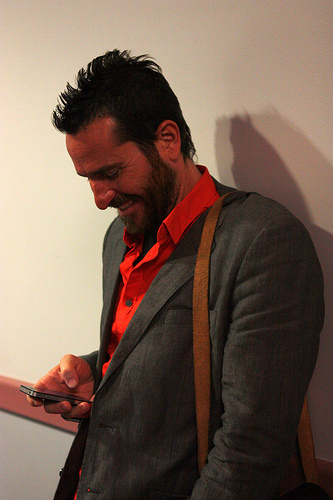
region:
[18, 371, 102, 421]
Small black mobile phone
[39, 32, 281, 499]
Man wearing a red shirt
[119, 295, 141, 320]
Small grey button on shirt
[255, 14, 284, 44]
PArt of white wall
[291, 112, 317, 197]
Part of white wall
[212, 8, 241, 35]
Part of white wall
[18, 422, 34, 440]
Part of white wall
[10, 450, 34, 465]
Part of white wall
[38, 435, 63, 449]
Part of white wall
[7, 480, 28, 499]
Part of white wall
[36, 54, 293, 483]
This is a man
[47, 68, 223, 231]
The man is smiling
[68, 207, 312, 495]
The man is wearing a blazer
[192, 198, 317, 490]
The man is holding a bag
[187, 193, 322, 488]
The bag has a brown strap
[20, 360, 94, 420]
The man is holding a cell phone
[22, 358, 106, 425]
The cell phone is in the man's right hand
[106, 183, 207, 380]
The man has a red shirt under his blazer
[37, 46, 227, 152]
The man's hair is styled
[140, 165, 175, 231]
The man has a beard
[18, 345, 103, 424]
hand holding electronic device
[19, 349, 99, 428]
cell phone in a hand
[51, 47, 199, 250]
dark haired man smiling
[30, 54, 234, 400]
person with a beard and mustache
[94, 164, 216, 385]
orange shirt with buttons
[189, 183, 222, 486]
long brown shouder strap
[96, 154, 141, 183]
eye with crow's feet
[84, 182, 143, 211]
mustache under a nose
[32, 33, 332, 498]
man leaning against a wall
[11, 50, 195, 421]
man looking at cell phone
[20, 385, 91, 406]
The Iphone in the mans hands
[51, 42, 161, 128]
The guys fauxhawk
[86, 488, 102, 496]
The button holes on the mans jacket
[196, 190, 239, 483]
The strap of the mans bag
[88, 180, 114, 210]
The mans nose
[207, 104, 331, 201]
The shadow of the man on the wall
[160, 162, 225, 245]
The collar of the mans shirt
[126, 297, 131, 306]
The buttons on the mans red shirt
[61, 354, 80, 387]
The mans bent thumb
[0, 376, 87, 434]
The pink stripe on the wall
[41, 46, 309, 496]
man standing against the wall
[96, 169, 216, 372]
collared orange shirt of man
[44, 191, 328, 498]
gray jacket of m an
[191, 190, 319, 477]
brown strap of man's bag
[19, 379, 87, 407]
man's cellphone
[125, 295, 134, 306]
button on the orange shirt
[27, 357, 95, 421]
hand holding the cellphone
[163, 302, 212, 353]
breast pocket on gray coat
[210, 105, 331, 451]
man's shadow on the wall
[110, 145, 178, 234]
facial hair of the man